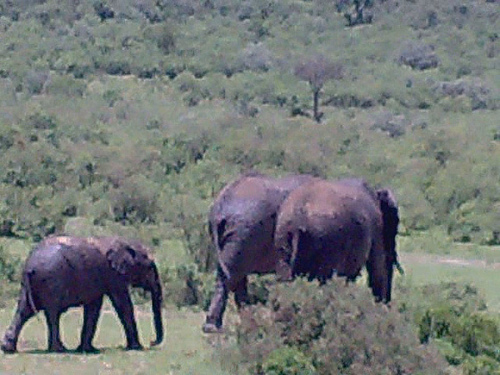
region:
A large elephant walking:
[277, 183, 397, 334]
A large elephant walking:
[203, 181, 304, 325]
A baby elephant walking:
[0, 245, 174, 352]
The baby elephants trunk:
[146, 276, 171, 354]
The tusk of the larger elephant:
[393, 255, 407, 275]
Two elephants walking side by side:
[190, 171, 415, 346]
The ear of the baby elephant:
[106, 242, 143, 283]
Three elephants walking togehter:
[0, 136, 401, 360]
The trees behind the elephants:
[10, 16, 498, 231]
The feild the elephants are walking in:
[15, 243, 472, 371]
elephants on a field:
[2, 156, 416, 373]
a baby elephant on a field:
[7, 215, 175, 366]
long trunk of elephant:
[145, 275, 170, 350]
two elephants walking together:
[190, 163, 414, 353]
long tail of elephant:
[201, 219, 241, 291]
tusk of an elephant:
[390, 246, 411, 286]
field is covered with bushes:
[10, 9, 498, 371]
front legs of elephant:
[75, 291, 146, 355]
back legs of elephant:
[1, 309, 66, 357]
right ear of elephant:
[102, 241, 142, 282]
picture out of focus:
[3, 38, 494, 345]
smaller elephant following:
[6, 230, 184, 352]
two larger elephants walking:
[188, 181, 435, 330]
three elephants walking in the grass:
[1, 148, 461, 350]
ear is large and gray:
[103, 227, 130, 292]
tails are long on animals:
[191, 220, 318, 280]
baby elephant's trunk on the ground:
[140, 263, 178, 356]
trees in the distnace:
[60, 100, 465, 170]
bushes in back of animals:
[258, 286, 491, 369]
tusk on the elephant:
[386, 251, 406, 283]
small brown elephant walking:
[24, 217, 171, 370]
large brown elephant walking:
[191, 155, 279, 343]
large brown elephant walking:
[254, 159, 412, 298]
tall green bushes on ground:
[34, 22, 128, 75]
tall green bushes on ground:
[256, 56, 314, 110]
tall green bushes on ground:
[113, 81, 165, 131]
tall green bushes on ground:
[400, 29, 448, 69]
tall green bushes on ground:
[397, 59, 435, 117]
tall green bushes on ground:
[159, 74, 211, 114]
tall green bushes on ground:
[34, 55, 68, 96]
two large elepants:
[143, 176, 424, 283]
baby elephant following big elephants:
[0, 228, 200, 372]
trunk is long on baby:
[126, 260, 164, 352]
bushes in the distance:
[0, 78, 471, 173]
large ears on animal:
[383, 195, 403, 277]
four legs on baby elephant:
[0, 302, 155, 359]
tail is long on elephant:
[199, 216, 227, 290]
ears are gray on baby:
[106, 235, 128, 282]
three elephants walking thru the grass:
[1, 159, 421, 352]